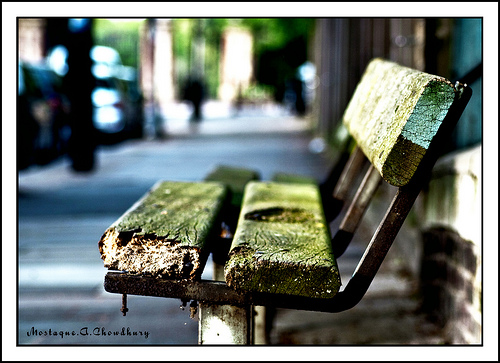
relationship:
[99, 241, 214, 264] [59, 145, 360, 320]
edge of wood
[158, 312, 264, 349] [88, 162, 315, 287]
leg under brace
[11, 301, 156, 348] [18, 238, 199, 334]
name in lower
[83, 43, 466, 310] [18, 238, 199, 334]
bench on ground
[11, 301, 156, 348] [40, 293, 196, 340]
name in bottom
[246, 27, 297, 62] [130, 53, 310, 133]
tree in distance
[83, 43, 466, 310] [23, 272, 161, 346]
bench next to ground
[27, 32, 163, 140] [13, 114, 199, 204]
car next to curb